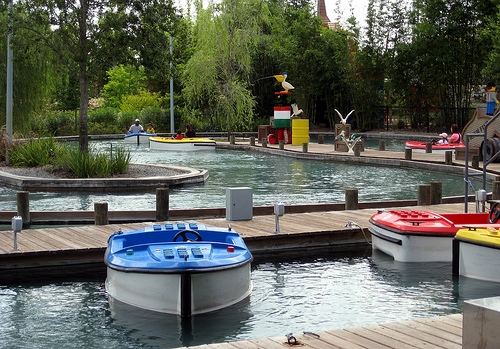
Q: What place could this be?
A: It is a pond.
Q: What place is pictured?
A: It is a pond.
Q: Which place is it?
A: It is a pond.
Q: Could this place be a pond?
A: Yes, it is a pond.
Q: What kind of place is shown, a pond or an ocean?
A: It is a pond.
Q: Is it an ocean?
A: No, it is a pond.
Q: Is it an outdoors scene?
A: Yes, it is outdoors.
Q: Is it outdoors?
A: Yes, it is outdoors.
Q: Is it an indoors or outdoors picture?
A: It is outdoors.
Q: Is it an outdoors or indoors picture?
A: It is outdoors.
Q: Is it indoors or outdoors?
A: It is outdoors.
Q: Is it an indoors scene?
A: No, it is outdoors.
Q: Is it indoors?
A: No, it is outdoors.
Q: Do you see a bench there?
A: No, there are no benches.